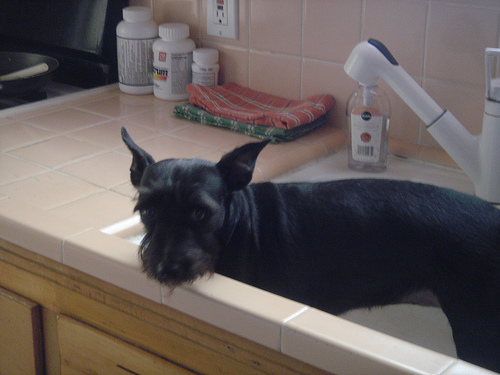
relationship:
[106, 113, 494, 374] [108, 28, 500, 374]
dog in a sink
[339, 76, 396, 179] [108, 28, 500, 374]
soap on a sink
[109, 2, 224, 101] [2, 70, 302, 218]
bottles on a counter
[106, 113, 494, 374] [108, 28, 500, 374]
dog in sink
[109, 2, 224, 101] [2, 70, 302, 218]
vitamins are on counter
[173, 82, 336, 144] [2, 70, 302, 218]
couple on counter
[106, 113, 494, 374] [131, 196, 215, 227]
dog looking straight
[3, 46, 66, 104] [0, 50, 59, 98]
pot on pot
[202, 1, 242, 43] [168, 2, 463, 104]
plug on wall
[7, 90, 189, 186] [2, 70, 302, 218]
tile on counter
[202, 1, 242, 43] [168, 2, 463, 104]
outlet in wall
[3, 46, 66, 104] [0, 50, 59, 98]
pan on pot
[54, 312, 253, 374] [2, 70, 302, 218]
cabinet below counter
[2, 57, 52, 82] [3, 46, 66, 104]
utensil in pan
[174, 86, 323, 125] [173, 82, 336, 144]
couple of couple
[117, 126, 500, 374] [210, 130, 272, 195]
dog right ear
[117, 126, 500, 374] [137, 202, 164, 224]
dog left eye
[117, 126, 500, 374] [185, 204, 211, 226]
dog right eye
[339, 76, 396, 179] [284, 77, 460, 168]
bottle of soap on sink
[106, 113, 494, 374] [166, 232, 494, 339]
dog taking a bath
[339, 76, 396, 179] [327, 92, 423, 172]
bottle of a hand soap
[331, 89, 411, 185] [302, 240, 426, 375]
bottle of hand soap on sink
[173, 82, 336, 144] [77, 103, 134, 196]
couple for hand are on counter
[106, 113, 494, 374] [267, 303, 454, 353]
dog ready to get a bath